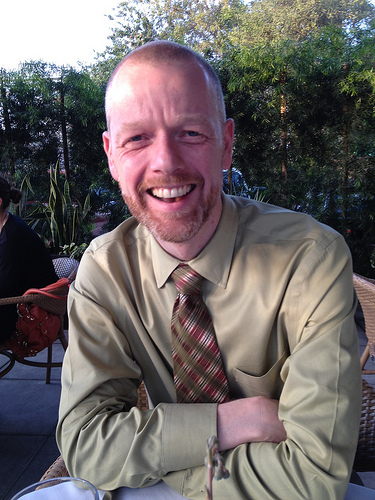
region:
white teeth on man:
[136, 184, 204, 202]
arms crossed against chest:
[153, 403, 346, 498]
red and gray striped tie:
[164, 273, 240, 397]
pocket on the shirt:
[238, 358, 285, 396]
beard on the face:
[129, 185, 217, 227]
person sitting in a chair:
[0, 194, 59, 277]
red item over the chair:
[12, 277, 66, 346]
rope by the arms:
[200, 433, 226, 499]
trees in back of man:
[237, 55, 374, 165]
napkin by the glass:
[19, 484, 107, 499]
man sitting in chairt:
[18, 42, 357, 487]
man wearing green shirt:
[61, 190, 373, 481]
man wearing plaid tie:
[143, 254, 244, 443]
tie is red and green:
[148, 261, 235, 411]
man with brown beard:
[111, 164, 237, 250]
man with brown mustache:
[126, 159, 200, 200]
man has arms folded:
[40, 352, 360, 499]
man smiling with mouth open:
[135, 167, 206, 224]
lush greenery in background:
[6, 5, 372, 264]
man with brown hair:
[73, 36, 248, 108]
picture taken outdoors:
[12, 79, 374, 492]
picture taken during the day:
[11, 52, 86, 65]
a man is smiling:
[150, 181, 198, 205]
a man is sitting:
[37, 167, 371, 498]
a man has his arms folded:
[40, 339, 355, 496]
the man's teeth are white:
[155, 191, 188, 194]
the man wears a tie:
[171, 263, 265, 441]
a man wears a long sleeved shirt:
[74, 268, 369, 498]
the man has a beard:
[120, 180, 226, 250]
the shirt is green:
[255, 259, 318, 336]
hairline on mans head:
[130, 60, 193, 73]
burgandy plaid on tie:
[181, 312, 186, 325]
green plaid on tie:
[179, 329, 189, 337]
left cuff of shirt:
[169, 406, 212, 457]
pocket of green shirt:
[241, 365, 280, 396]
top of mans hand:
[225, 398, 260, 440]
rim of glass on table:
[26, 475, 72, 484]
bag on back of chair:
[36, 284, 64, 296]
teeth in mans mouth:
[156, 189, 187, 197]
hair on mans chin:
[148, 217, 209, 242]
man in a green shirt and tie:
[60, 40, 358, 499]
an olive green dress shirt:
[60, 198, 360, 499]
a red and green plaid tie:
[168, 266, 230, 403]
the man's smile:
[148, 183, 193, 200]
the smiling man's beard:
[121, 173, 222, 240]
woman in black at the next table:
[0, 179, 57, 326]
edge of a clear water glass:
[10, 478, 101, 498]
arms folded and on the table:
[61, 399, 344, 494]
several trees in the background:
[2, 0, 364, 217]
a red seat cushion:
[8, 281, 66, 357]